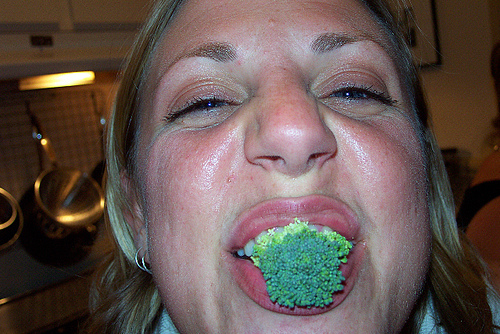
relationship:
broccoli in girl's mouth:
[248, 218, 353, 309] [224, 195, 370, 319]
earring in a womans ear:
[113, 238, 156, 271] [115, 164, 146, 311]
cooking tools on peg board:
[5, 89, 110, 276] [0, 87, 114, 167]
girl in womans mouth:
[103, 0, 458, 332] [213, 193, 380, 323]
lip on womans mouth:
[228, 194, 363, 250] [209, 212, 359, 327]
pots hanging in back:
[2, 52, 132, 270] [14, 273, 75, 334]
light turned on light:
[20, 69, 96, 91] [17, 61, 109, 91]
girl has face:
[103, 0, 458, 332] [156, 0, 426, 331]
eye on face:
[317, 70, 391, 120] [156, 0, 426, 331]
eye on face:
[170, 82, 237, 128] [156, 0, 426, 331]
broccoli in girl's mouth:
[268, 232, 338, 287] [224, 197, 370, 319]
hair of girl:
[96, 4, 498, 327] [103, 0, 438, 332]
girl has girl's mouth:
[103, 0, 438, 332] [224, 195, 370, 319]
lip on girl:
[228, 194, 363, 250] [103, 0, 458, 332]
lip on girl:
[224, 239, 365, 315] [103, 0, 458, 332]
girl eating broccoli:
[103, 0, 458, 332] [248, 218, 353, 309]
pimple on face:
[268, 16, 278, 28] [129, 2, 434, 329]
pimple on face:
[223, 169, 237, 184] [129, 2, 434, 329]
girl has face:
[103, 0, 458, 332] [129, 2, 434, 329]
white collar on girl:
[407, 288, 455, 332] [103, 0, 458, 332]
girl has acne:
[103, 0, 458, 332] [155, 112, 423, 228]